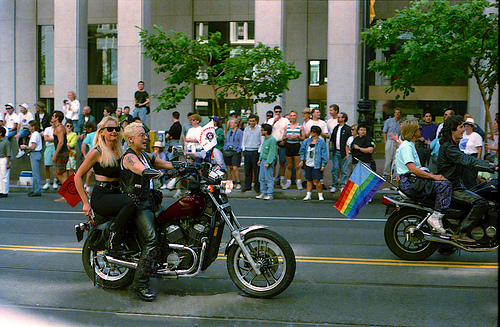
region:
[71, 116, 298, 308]
two people riding a motorcycle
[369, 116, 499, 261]
two people riding a motorcycle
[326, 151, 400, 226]
a rainbow flag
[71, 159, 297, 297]
a black and chrome motorcycle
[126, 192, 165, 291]
black leather chaps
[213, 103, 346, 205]
a group of spectators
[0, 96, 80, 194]
a group of spectators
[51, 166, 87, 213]
a red flag with black circle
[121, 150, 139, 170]
a tattoo on a man's right arm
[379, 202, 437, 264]
a motorcycle rear tire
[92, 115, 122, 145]
the head of a woman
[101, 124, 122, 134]
a pair of sunglasses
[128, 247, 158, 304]
a black boot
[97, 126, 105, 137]
the ear of a woman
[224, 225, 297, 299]
a black motorcycle tire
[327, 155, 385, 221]
a rainbow flag on the motorcycle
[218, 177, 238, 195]
a headlight on the motorcycle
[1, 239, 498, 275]
a yellow line in the road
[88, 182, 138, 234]
a pair of black pants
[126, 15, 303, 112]
a small green tree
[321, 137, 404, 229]
this is a pride flag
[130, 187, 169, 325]
these are leather chaps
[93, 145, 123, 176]
this is crop top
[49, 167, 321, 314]
this is a motorcycle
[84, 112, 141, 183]
this is blonde hair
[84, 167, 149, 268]
these are black pants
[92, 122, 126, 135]
these are sun glasses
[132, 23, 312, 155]
this is a tree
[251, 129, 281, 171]
this is a green shirt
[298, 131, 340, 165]
this is a blue jacket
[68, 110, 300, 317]
two women on a motorcycle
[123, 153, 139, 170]
dark tattoo on the upper arm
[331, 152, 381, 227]
rainbow flag blowing in the wind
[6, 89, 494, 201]
spectators standing on the side of the street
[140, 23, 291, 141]
small green tree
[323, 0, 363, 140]
light colored pillar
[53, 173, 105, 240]
red flag on the bag of the bike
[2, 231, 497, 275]
yellow lane lines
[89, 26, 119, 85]
reflections on the glass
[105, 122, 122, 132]
dark sunglasses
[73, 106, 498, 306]
people riding motorcycles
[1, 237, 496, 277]
yellow lines on street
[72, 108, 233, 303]
two people on a motorcycle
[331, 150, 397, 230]
a colorful flag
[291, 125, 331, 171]
person wearing a blue jacket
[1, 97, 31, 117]
two people wearing hats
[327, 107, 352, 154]
man wearing a black jacket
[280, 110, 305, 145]
person wearing blue and white striped shirt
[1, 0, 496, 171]
large building behind people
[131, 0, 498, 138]
trees